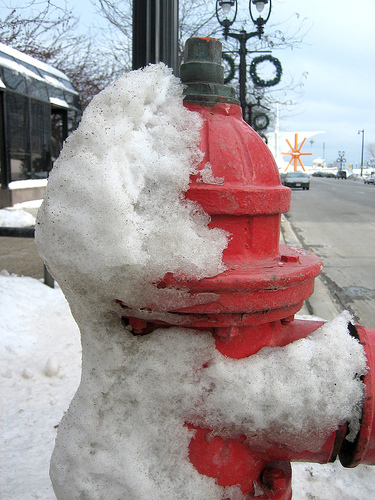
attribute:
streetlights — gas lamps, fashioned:
[215, 6, 305, 64]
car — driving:
[293, 169, 323, 193]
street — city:
[284, 199, 374, 291]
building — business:
[1, 68, 114, 218]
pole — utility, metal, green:
[123, 2, 185, 74]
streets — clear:
[287, 184, 372, 288]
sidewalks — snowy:
[9, 170, 63, 229]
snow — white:
[60, 347, 156, 464]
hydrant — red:
[91, 77, 307, 398]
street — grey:
[287, 201, 370, 297]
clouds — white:
[279, 43, 356, 115]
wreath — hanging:
[246, 51, 292, 108]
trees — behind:
[19, 8, 173, 112]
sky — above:
[223, 12, 368, 98]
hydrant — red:
[150, 77, 370, 451]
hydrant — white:
[105, 84, 304, 426]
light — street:
[214, 0, 284, 120]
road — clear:
[286, 173, 373, 325]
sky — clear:
[0, 2, 374, 164]